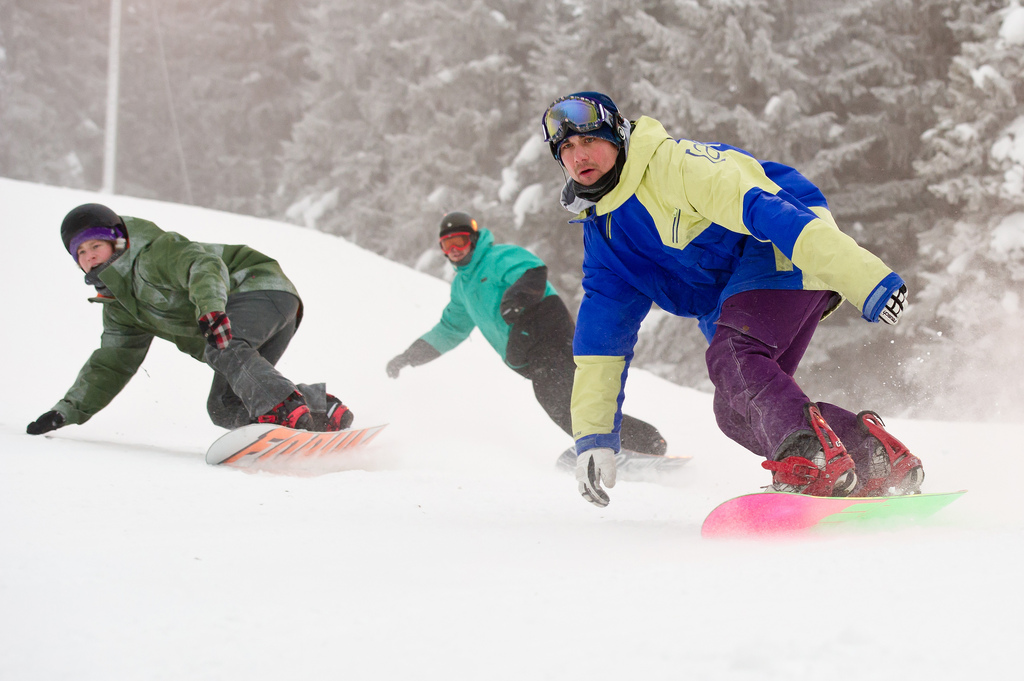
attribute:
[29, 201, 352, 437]
snow boarder — green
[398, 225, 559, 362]
greem coat — teal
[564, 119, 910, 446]
snowboarder — black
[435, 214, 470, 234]
googles — red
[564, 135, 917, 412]
winter coat — yellow, blue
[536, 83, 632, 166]
helmet — black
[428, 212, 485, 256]
helmet — black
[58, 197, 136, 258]
helmet — black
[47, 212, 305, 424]
coat — dark green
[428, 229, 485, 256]
goggles — red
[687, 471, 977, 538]
snowboard — pink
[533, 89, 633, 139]
goggles — black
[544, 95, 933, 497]
snowboarder — yellow, blue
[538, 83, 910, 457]
jacket — yellow and blue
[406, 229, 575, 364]
jacket — green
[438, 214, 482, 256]
goggles — orange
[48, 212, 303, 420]
jacket — green, gray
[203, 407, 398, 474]
snowboard — white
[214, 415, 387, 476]
letters — orange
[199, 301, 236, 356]
glove — plaid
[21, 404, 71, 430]
glove — plaid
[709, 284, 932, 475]
ski pants — purple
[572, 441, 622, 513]
glove — white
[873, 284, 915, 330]
glove — white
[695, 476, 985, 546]
snowboard — pink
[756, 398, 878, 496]
boot mount — red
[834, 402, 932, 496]
boot mount — red